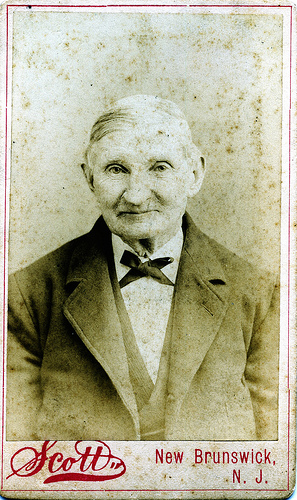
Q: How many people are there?
A: 1.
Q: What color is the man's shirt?
A: White.